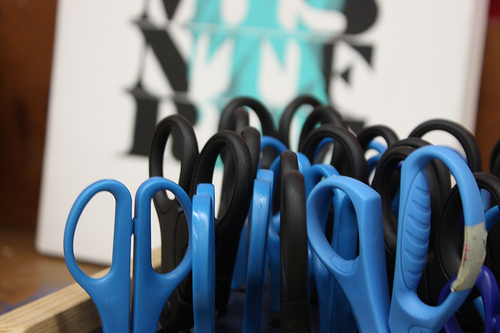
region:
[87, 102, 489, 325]
Collection of scissors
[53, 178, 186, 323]
Blue pair of scissors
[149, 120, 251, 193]
Black pair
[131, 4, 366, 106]
Words in background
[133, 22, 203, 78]
Letter N is black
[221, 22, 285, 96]
Letter T is blue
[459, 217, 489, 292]
Part of handle is gray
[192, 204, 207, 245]
Shiny part of plastic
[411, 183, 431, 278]
Part of corrugated handle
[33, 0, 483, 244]
Behind scissors is white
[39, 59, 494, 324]
a collection of scissors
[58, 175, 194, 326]
a pair of blue scissors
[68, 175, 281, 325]
three pairs of blue scissors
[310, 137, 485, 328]
tape around handle of scissors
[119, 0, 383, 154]
black and blue print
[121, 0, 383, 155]
black and blue letters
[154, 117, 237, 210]
handle of black scissors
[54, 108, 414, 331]
a grouping of scissors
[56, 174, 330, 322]
four pairs of scissors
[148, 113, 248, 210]
handles of black scissors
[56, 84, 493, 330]
A large bunch of scissors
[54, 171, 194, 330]
A pair of blue scissors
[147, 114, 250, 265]
A pair of black scissors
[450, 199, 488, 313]
Tape on the side of scissors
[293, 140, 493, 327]
Scissor handles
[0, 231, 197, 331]
The side of a wood container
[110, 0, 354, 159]
Blue and black lettering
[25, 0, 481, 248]
A white canvas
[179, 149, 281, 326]
Scissors turned sideways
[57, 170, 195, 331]
Scissors facing towards the front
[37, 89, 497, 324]
black and blue scissors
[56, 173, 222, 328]
scissors with blue handles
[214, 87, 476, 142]
scissors with black handles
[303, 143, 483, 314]
right handle of scissors is big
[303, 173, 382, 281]
left handle of scissors is small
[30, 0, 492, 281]
a white board behind a bunch scissors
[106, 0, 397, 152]
black and turquoise letters on board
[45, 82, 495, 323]
scissors are stand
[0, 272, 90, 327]
scissors are next to wood surface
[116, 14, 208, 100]
Letter N on board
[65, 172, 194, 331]
Scissors are blue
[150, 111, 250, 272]
Scissors are black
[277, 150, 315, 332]
Black scissors next to blue scissors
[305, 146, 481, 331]
Blue scissors in front of black scissors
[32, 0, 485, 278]
Artwork behind scissors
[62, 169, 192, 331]
Scissors in a wooden box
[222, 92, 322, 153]
Black scissors next to scissors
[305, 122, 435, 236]
Black scissors behind blue scissors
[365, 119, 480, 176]
Black scissors behind black scissors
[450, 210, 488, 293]
Tape on blue scissors